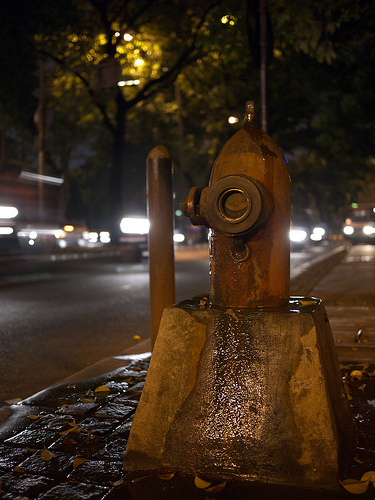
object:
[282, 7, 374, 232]
tree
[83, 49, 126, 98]
sign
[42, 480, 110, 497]
brick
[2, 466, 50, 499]
brick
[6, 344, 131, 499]
sidewalk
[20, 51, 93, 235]
tree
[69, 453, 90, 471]
leaf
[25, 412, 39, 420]
leaf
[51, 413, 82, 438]
leaf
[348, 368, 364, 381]
leaf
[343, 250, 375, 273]
ground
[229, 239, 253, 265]
ring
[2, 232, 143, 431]
road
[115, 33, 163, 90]
lights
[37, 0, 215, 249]
tree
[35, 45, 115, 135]
branch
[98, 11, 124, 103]
branch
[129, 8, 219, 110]
branch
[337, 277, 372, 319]
ground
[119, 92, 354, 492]
structure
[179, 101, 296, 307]
fire hydrant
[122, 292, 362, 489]
cement block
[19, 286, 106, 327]
ground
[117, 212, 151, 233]
light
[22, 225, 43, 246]
light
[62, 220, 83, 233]
light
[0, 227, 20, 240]
light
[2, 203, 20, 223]
light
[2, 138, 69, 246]
business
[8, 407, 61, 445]
brick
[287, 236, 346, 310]
sidewalk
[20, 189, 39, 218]
wall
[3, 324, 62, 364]
ground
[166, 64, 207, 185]
tree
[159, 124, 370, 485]
street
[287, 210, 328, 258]
cars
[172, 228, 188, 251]
lights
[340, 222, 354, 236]
headlight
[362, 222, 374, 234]
headlight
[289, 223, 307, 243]
headlight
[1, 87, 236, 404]
street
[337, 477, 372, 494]
leaf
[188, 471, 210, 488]
leaf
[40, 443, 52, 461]
leaf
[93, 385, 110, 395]
leaf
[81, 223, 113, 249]
car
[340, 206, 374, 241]
car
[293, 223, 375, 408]
road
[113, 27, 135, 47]
street light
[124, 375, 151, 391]
brick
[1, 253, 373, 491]
sidewalk